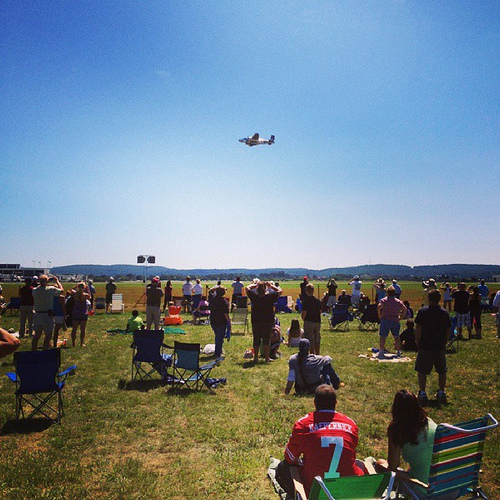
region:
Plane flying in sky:
[236, 131, 284, 151]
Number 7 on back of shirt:
[313, 431, 359, 479]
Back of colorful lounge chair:
[428, 417, 499, 498]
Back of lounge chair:
[169, 341, 213, 389]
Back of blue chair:
[7, 347, 77, 421]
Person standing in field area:
[408, 287, 455, 404]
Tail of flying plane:
[265, 129, 278, 141]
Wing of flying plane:
[248, 128, 265, 140]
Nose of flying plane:
[236, 136, 244, 144]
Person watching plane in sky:
[208, 282, 233, 362]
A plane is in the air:
[226, 124, 286, 156]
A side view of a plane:
[234, 128, 279, 155]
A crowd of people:
[0, 273, 496, 495]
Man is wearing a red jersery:
[278, 402, 363, 487]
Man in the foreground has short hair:
[300, 380, 345, 415]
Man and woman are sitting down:
[264, 385, 499, 490]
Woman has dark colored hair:
[379, 383, 450, 488]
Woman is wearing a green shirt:
[384, 408, 450, 488]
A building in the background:
[1, 256, 56, 282]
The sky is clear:
[4, 2, 499, 268]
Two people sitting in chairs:
[265, 383, 496, 499]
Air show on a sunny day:
[0, 118, 497, 498]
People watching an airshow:
[1, 271, 498, 498]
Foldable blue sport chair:
[6, 343, 77, 423]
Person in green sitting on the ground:
[124, 308, 146, 335]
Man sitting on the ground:
[276, 336, 346, 393]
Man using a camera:
[27, 270, 65, 349]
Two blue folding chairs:
[128, 324, 224, 396]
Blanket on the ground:
[356, 346, 411, 366]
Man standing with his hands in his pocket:
[408, 285, 455, 401]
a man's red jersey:
[282, 405, 359, 481]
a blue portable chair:
[161, 338, 214, 388]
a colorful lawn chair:
[422, 412, 496, 498]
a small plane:
[232, 132, 279, 150]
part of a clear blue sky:
[0, 33, 167, 116]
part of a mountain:
[337, 259, 498, 279]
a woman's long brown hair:
[387, 385, 433, 446]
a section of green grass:
[323, 323, 370, 348]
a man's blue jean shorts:
[30, 308, 55, 334]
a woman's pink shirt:
[197, 297, 209, 314]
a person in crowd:
[289, 342, 329, 380]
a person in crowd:
[308, 387, 373, 474]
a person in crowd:
[384, 396, 443, 469]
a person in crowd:
[379, 289, 404, 353]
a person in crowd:
[304, 284, 331, 334]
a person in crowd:
[287, 318, 308, 344]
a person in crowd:
[201, 282, 248, 346]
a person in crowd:
[139, 266, 174, 319]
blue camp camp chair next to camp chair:
[129, 327, 224, 393]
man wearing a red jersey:
[279, 383, 359, 490]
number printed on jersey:
[321, 435, 344, 477]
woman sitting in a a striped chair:
[377, 387, 499, 499]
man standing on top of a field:
[410, 286, 455, 402]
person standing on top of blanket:
[361, 285, 412, 364]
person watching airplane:
[204, 285, 235, 363]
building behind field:
[0, 262, 52, 280]